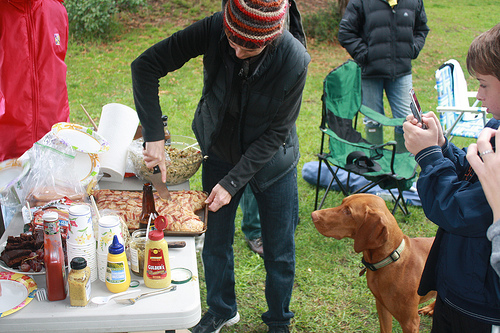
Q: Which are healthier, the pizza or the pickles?
A: The pickles are healthier than the pizza.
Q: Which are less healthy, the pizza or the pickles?
A: The pizza are less healthy than the pickles.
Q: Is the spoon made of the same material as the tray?
A: No, the spoon is made of plastic and the tray is made of metal.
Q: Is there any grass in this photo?
A: Yes, there is grass.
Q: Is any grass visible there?
A: Yes, there is grass.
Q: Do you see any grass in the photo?
A: Yes, there is grass.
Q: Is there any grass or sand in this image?
A: Yes, there is grass.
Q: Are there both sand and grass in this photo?
A: No, there is grass but no sand.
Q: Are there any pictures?
A: No, there are no pictures.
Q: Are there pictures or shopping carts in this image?
A: No, there are no pictures or shopping carts.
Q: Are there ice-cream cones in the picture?
A: No, there are no ice-cream cones.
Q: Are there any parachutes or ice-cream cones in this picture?
A: No, there are no ice-cream cones or parachutes.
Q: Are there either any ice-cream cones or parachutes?
A: No, there are no ice-cream cones or parachutes.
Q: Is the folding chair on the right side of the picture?
A: Yes, the folding chair is on the right of the image.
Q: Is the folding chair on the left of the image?
A: No, the folding chair is on the right of the image.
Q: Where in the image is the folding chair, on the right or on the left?
A: The folding chair is on the right of the image.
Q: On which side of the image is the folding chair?
A: The folding chair is on the right of the image.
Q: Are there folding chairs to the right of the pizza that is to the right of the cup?
A: Yes, there is a folding chair to the right of the pizza.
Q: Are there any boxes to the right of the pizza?
A: No, there is a folding chair to the right of the pizza.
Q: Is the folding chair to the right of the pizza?
A: Yes, the folding chair is to the right of the pizza.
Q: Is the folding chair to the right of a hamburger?
A: No, the folding chair is to the right of the pizza.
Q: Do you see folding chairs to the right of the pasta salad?
A: Yes, there is a folding chair to the right of the pasta salad.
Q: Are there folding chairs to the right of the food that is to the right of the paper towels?
A: Yes, there is a folding chair to the right of the pasta salad.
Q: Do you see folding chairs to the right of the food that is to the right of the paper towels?
A: Yes, there is a folding chair to the right of the pasta salad.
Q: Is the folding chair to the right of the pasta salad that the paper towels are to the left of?
A: Yes, the folding chair is to the right of the pasta salad.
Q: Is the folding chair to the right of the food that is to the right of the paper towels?
A: Yes, the folding chair is to the right of the pasta salad.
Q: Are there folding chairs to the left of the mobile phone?
A: Yes, there is a folding chair to the left of the mobile phone.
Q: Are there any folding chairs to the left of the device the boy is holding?
A: Yes, there is a folding chair to the left of the mobile phone.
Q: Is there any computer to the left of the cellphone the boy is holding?
A: No, there is a folding chair to the left of the mobile phone.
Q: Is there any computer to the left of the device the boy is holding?
A: No, there is a folding chair to the left of the mobile phone.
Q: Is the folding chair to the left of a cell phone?
A: Yes, the folding chair is to the left of a cell phone.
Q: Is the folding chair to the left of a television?
A: No, the folding chair is to the left of a cell phone.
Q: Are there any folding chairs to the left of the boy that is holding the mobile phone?
A: Yes, there is a folding chair to the left of the boy.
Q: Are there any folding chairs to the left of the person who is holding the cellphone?
A: Yes, there is a folding chair to the left of the boy.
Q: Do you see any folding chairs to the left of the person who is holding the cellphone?
A: Yes, there is a folding chair to the left of the boy.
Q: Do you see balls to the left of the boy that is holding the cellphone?
A: No, there is a folding chair to the left of the boy.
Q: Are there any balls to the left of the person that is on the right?
A: No, there is a folding chair to the left of the boy.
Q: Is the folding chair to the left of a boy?
A: Yes, the folding chair is to the left of a boy.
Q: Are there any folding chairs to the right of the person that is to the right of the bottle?
A: Yes, there is a folding chair to the right of the person.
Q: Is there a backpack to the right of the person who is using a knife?
A: No, there is a folding chair to the right of the person.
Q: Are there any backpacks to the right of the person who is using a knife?
A: No, there is a folding chair to the right of the person.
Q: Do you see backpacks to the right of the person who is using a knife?
A: No, there is a folding chair to the right of the person.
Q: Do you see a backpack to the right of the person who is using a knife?
A: No, there is a folding chair to the right of the person.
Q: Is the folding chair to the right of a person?
A: Yes, the folding chair is to the right of a person.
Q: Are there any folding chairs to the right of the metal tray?
A: Yes, there is a folding chair to the right of the tray.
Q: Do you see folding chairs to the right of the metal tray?
A: Yes, there is a folding chair to the right of the tray.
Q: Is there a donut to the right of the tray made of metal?
A: No, there is a folding chair to the right of the tray.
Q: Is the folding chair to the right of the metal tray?
A: Yes, the folding chair is to the right of the tray.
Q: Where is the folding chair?
A: The folding chair is on the grass.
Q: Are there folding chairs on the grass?
A: Yes, there is a folding chair on the grass.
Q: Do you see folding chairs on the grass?
A: Yes, there is a folding chair on the grass.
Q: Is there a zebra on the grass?
A: No, there is a folding chair on the grass.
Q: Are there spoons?
A: Yes, there is a spoon.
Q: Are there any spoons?
A: Yes, there is a spoon.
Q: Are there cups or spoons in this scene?
A: Yes, there is a spoon.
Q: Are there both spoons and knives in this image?
A: Yes, there are both a spoon and a knife.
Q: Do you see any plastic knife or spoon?
A: Yes, there is a plastic spoon.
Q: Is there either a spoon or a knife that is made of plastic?
A: Yes, the spoon is made of plastic.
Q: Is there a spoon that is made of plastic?
A: Yes, there is a spoon that is made of plastic.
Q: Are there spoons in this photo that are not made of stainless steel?
A: Yes, there is a spoon that is made of plastic.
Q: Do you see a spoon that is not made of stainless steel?
A: Yes, there is a spoon that is made of plastic.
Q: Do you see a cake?
A: No, there are no cakes.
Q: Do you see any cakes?
A: No, there are no cakes.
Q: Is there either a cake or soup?
A: No, there are no cakes or soup.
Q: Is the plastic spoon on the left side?
A: Yes, the spoon is on the left of the image.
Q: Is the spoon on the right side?
A: No, the spoon is on the left of the image.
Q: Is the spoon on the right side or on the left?
A: The spoon is on the left of the image.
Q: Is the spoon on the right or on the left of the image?
A: The spoon is on the left of the image.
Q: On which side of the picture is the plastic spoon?
A: The spoon is on the left of the image.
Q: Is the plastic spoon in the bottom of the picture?
A: Yes, the spoon is in the bottom of the image.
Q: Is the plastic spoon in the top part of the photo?
A: No, the spoon is in the bottom of the image.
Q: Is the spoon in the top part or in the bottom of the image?
A: The spoon is in the bottom of the image.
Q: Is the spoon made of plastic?
A: Yes, the spoon is made of plastic.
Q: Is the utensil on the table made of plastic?
A: Yes, the spoon is made of plastic.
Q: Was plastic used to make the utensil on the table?
A: Yes, the spoon is made of plastic.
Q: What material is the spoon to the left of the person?
A: The spoon is made of plastic.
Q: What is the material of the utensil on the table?
A: The spoon is made of plastic.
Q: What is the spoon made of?
A: The spoon is made of plastic.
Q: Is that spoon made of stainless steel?
A: No, the spoon is made of plastic.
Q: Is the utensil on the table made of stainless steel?
A: No, the spoon is made of plastic.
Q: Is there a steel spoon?
A: No, there is a spoon but it is made of plastic.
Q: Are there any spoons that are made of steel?
A: No, there is a spoon but it is made of plastic.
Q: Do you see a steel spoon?
A: No, there is a spoon but it is made of plastic.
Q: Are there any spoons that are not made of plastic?
A: No, there is a spoon but it is made of plastic.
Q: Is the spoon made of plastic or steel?
A: The spoon is made of plastic.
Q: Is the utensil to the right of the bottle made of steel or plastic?
A: The spoon is made of plastic.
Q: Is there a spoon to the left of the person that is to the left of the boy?
A: Yes, there is a spoon to the left of the person.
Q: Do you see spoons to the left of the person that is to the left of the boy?
A: Yes, there is a spoon to the left of the person.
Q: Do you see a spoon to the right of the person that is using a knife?
A: No, the spoon is to the left of the person.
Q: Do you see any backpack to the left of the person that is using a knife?
A: No, there is a spoon to the left of the person.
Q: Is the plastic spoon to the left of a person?
A: Yes, the spoon is to the left of a person.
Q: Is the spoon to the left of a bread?
A: No, the spoon is to the left of a person.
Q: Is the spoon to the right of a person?
A: No, the spoon is to the left of a person.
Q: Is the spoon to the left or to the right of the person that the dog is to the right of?
A: The spoon is to the left of the person.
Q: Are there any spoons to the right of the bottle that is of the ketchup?
A: Yes, there is a spoon to the right of the bottle.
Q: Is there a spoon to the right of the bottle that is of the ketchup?
A: Yes, there is a spoon to the right of the bottle.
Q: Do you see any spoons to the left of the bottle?
A: No, the spoon is to the right of the bottle.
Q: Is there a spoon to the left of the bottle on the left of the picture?
A: No, the spoon is to the right of the bottle.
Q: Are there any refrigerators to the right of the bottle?
A: No, there is a spoon to the right of the bottle.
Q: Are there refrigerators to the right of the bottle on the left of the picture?
A: No, there is a spoon to the right of the bottle.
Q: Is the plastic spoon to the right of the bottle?
A: Yes, the spoon is to the right of the bottle.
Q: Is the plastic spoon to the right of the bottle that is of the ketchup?
A: Yes, the spoon is to the right of the bottle.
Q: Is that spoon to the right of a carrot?
A: No, the spoon is to the right of the bottle.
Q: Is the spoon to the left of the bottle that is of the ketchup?
A: No, the spoon is to the right of the bottle.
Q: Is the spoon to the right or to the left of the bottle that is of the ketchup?
A: The spoon is to the right of the bottle.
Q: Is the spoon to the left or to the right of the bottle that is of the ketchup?
A: The spoon is to the right of the bottle.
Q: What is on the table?
A: The spoon is on the table.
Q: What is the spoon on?
A: The spoon is on the table.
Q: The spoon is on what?
A: The spoon is on the table.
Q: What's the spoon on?
A: The spoon is on the table.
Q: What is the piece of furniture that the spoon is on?
A: The piece of furniture is a table.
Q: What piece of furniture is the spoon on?
A: The spoon is on the table.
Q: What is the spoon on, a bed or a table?
A: The spoon is on a table.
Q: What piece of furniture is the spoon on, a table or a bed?
A: The spoon is on a table.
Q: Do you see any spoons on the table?
A: Yes, there is a spoon on the table.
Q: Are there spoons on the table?
A: Yes, there is a spoon on the table.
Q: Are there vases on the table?
A: No, there is a spoon on the table.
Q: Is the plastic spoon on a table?
A: Yes, the spoon is on a table.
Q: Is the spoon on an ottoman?
A: No, the spoon is on a table.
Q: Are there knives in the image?
A: Yes, there is a knife.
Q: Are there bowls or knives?
A: Yes, there is a knife.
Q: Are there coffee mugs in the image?
A: No, there are no coffee mugs.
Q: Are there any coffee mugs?
A: No, there are no coffee mugs.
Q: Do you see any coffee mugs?
A: No, there are no coffee mugs.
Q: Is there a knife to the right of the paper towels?
A: Yes, there is a knife to the right of the paper towels.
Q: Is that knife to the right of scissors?
A: No, the knife is to the right of the paper towels.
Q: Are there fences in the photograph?
A: No, there are no fences.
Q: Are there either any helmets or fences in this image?
A: No, there are no fences or helmets.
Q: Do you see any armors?
A: No, there are no armors.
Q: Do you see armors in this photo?
A: No, there are no armors.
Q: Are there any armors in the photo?
A: No, there are no armors.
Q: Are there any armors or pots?
A: No, there are no armors or pots.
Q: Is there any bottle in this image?
A: Yes, there is a bottle.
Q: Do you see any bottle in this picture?
A: Yes, there is a bottle.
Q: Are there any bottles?
A: Yes, there is a bottle.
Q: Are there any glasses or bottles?
A: Yes, there is a bottle.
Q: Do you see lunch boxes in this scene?
A: No, there are no lunch boxes.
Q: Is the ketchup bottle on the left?
A: Yes, the bottle is on the left of the image.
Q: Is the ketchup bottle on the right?
A: No, the bottle is on the left of the image.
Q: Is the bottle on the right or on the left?
A: The bottle is on the left of the image.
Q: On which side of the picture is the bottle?
A: The bottle is on the left of the image.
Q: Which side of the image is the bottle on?
A: The bottle is on the left of the image.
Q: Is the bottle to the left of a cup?
A: Yes, the bottle is to the left of a cup.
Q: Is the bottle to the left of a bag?
A: No, the bottle is to the left of a cup.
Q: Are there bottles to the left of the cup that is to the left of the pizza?
A: Yes, there is a bottle to the left of the cup.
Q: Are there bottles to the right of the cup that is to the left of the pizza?
A: No, the bottle is to the left of the cup.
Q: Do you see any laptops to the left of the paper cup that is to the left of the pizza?
A: No, there is a bottle to the left of the cup.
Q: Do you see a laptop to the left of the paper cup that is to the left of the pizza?
A: No, there is a bottle to the left of the cup.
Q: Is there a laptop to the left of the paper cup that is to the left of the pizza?
A: No, there is a bottle to the left of the cup.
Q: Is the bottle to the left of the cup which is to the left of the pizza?
A: Yes, the bottle is to the left of the cup.